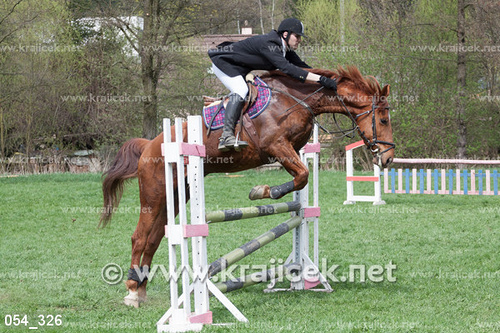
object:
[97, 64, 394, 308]
horse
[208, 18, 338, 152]
man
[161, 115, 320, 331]
gate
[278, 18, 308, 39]
cap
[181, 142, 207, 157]
board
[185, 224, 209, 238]
board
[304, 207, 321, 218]
board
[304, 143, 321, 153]
board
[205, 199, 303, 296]
obstacle bar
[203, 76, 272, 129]
saddle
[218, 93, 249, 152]
boots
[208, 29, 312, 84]
jacket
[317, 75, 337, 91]
glove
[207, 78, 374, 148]
bridle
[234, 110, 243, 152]
stirrup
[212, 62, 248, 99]
pants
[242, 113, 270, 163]
saddle strap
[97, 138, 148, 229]
tail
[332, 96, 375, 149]
reign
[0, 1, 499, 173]
trees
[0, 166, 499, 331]
field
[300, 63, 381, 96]
mane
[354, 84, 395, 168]
brown head